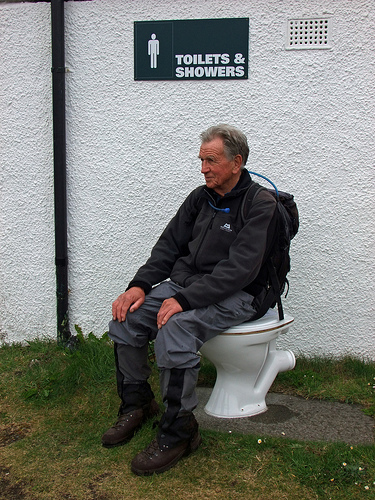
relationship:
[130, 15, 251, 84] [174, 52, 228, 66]
sign saying toilet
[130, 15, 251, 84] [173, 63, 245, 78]
sign saying shower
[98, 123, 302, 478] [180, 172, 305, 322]
man wearing backpack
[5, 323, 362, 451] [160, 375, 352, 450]
lawn with spot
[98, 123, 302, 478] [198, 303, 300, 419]
man sitting on toilet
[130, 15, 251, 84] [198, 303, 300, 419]
sign for toilet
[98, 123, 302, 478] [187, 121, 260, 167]
man with graying hair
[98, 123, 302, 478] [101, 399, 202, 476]
man wearing a jacket and boots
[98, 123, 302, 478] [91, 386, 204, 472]
man wearing boots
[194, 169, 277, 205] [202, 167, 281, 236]
microphone wrap around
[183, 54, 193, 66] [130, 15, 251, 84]
letter on sign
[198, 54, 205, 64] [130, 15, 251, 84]
letter on sign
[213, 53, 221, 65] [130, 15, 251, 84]
letter on sign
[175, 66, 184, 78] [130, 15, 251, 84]
letter on sign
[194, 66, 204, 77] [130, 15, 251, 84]
letter on sign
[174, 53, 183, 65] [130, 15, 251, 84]
letter on sign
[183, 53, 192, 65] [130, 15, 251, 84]
letter on sign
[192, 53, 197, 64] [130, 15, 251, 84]
letter on sign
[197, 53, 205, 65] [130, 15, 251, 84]
letter on sign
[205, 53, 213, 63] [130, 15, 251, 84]
letter on sign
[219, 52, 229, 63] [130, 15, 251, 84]
letter on sign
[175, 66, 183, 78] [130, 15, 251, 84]
letter on sign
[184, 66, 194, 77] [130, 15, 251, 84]
letter on sign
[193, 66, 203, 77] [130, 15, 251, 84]
letter on sign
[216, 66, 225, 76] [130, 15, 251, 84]
letter on sign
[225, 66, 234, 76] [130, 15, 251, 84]
letter on sign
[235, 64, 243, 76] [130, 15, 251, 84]
letter on sign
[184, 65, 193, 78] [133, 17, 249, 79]
letter on sign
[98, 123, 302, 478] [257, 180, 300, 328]
man wearing backpack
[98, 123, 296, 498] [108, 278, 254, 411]
man wearing pants